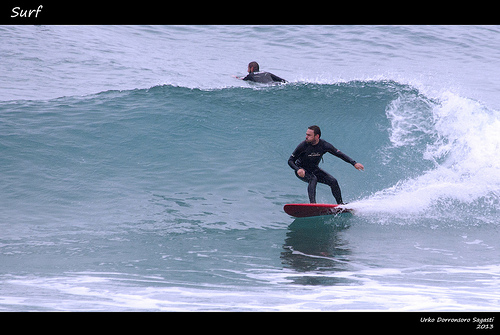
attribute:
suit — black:
[276, 121, 367, 210]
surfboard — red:
[277, 197, 354, 219]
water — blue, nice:
[4, 21, 499, 311]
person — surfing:
[254, 119, 376, 224]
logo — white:
[418, 315, 496, 333]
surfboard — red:
[278, 206, 357, 215]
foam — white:
[324, 71, 484, 221]